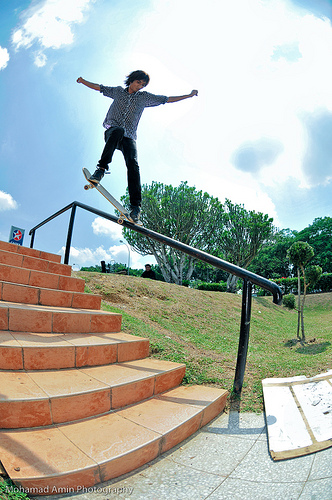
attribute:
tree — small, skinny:
[276, 230, 326, 359]